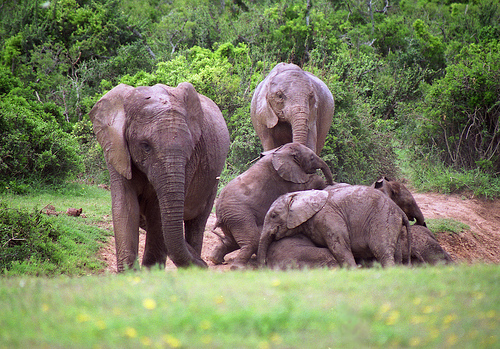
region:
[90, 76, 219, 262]
Large grey elephant standing in field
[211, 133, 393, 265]
Small elephants playing in mud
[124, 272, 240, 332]
Out of focus grass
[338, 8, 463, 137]
Forest filled with trees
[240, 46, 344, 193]
Female grey elephant in woods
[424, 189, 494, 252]
Mud with a little grass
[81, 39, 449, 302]
A family of elephants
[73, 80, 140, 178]
An elephant ear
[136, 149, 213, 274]
A large elephant trunk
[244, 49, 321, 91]
The top of an elephants head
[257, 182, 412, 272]
a young elephant plays with his mother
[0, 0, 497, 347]
a herd of elephants play in the field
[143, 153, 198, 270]
an elephants trunk has horizontal ridges on it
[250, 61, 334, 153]
an adult elephant looks on at the young elephants playing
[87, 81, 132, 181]
the large elephant ears signify that these elephants are from Africa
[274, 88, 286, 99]
the elephants eyes are small in relation to there head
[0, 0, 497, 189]
there is much vegitation behind the elephants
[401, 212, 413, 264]
the baby elephants tail is long and thin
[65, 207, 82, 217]
a pile of elephant poop is on the green grass behind the elephant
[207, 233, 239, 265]
the elephant leg is bent at the knee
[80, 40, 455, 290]
adult elephants and young elephants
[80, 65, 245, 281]
elephant with head slightly turned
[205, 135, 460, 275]
elephants playing in a pile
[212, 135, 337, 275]
elephant trying to climb to top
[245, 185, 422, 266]
elephant laying on one side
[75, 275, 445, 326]
grass with small yellow flowers growing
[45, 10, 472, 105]
screen of different kinds of trees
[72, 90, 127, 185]
ruffles along edge of ear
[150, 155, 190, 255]
rings of wrinkles across truck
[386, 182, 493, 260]
dirt to the side of young elephants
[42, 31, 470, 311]
elephants in a grassy area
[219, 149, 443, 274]
grey elephants in a pile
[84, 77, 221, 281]
large elephant looking forward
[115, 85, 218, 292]
elephant with long trunk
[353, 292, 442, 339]
little yellow flowers in grass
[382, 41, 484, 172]
trees in background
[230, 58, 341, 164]
old elephant in background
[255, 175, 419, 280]
small elephant laying on others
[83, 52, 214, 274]
elephant with large ears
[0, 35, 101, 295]
lots of green vegetation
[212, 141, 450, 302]
a pile of baby elephants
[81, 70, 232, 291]
a large elephant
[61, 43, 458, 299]
a herd of elephants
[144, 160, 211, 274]
the trunk of an elephant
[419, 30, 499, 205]
foliage behind the elephants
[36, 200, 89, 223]
elephant dung in the grass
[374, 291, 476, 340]
blurred yellow flowers in the grass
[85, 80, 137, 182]
an elephants ear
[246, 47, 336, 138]
the head of an elephant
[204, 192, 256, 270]
the back two legs and tail of a baby elephant